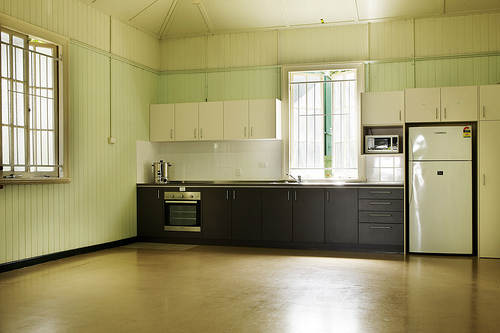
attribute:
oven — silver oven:
[145, 181, 205, 242]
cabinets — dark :
[148, 94, 276, 144]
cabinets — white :
[149, 81, 483, 141]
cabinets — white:
[359, 82, 498, 123]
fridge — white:
[406, 122, 475, 254]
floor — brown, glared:
[3, 236, 498, 328]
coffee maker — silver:
[150, 158, 176, 181]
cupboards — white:
[148, 98, 283, 147]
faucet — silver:
[276, 163, 311, 184]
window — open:
[5, 18, 71, 188]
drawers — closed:
[359, 185, 409, 251]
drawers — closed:
[360, 181, 407, 250]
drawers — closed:
[353, 182, 407, 249]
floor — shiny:
[53, 242, 234, 325]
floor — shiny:
[118, 253, 346, 324]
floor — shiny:
[102, 244, 315, 318]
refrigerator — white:
[401, 120, 476, 261]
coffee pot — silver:
[148, 157, 174, 186]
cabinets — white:
[146, 95, 287, 146]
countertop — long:
[139, 152, 393, 201]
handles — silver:
[283, 152, 328, 244]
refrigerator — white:
[410, 134, 477, 264]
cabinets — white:
[134, 86, 279, 153]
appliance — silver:
[145, 126, 186, 191]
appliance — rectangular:
[361, 106, 395, 173]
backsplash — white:
[123, 126, 315, 198]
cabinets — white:
[148, 68, 288, 175]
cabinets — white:
[154, 70, 283, 155]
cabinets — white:
[123, 92, 272, 144]